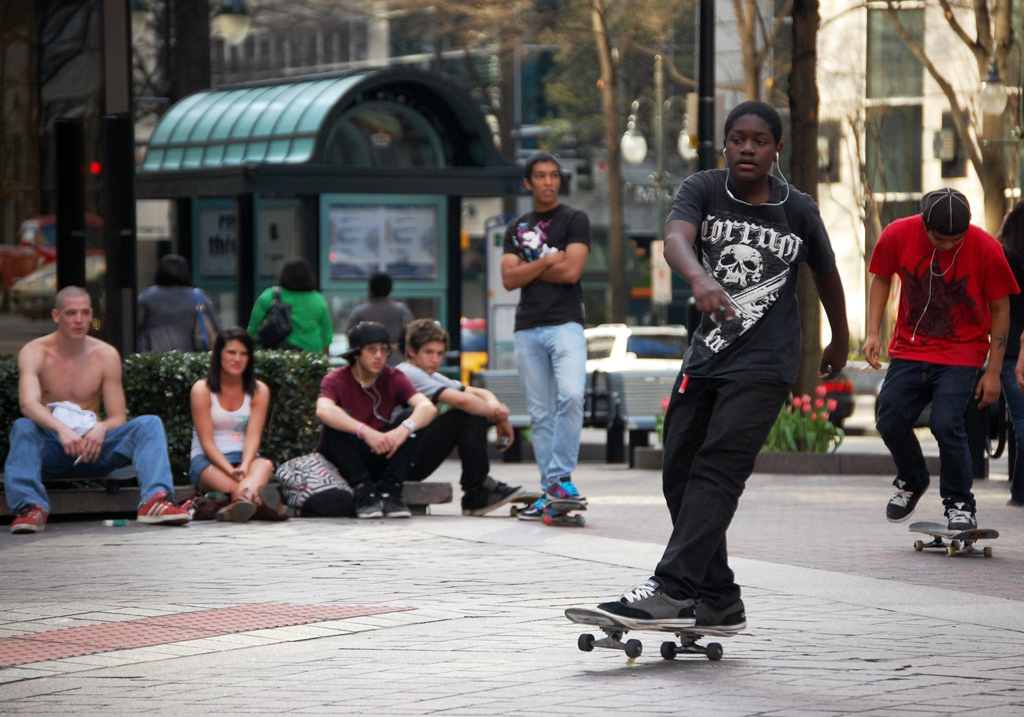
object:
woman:
[190, 328, 298, 520]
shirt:
[320, 364, 417, 434]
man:
[315, 322, 438, 521]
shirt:
[394, 364, 464, 424]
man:
[400, 317, 519, 515]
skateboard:
[509, 493, 586, 525]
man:
[503, 157, 591, 519]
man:
[15, 287, 192, 531]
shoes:
[136, 495, 189, 525]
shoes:
[11, 504, 49, 533]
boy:
[605, 100, 854, 626]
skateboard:
[565, 608, 739, 661]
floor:
[0, 523, 1024, 714]